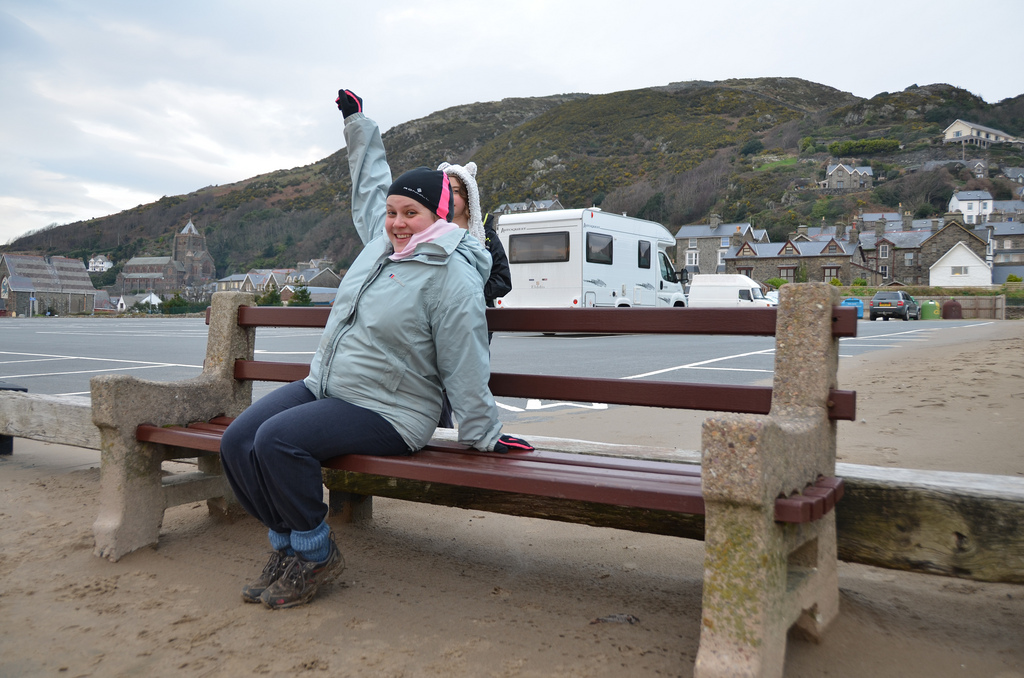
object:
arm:
[336, 89, 394, 244]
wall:
[726, 255, 795, 263]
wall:
[923, 240, 947, 256]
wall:
[972, 271, 991, 281]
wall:
[818, 259, 850, 263]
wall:
[967, 237, 975, 247]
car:
[870, 289, 919, 320]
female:
[213, 87, 528, 607]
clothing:
[217, 220, 527, 603]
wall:
[487, 212, 583, 310]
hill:
[610, 73, 1021, 191]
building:
[725, 236, 865, 294]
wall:
[751, 258, 781, 288]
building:
[941, 118, 1024, 147]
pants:
[217, 380, 404, 545]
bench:
[485, 208, 682, 309]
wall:
[698, 242, 717, 271]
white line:
[27, 352, 144, 377]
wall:
[915, 222, 986, 286]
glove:
[336, 89, 368, 119]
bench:
[88, 282, 855, 675]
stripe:
[436, 171, 447, 225]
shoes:
[239, 535, 343, 609]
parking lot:
[0, 308, 997, 399]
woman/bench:
[88, 89, 858, 669]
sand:
[0, 471, 1024, 678]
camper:
[490, 205, 685, 310]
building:
[904, 217, 1019, 318]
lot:
[0, 249, 1024, 520]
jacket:
[298, 114, 506, 458]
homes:
[674, 222, 754, 280]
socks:
[262, 522, 330, 563]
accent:
[386, 168, 454, 221]